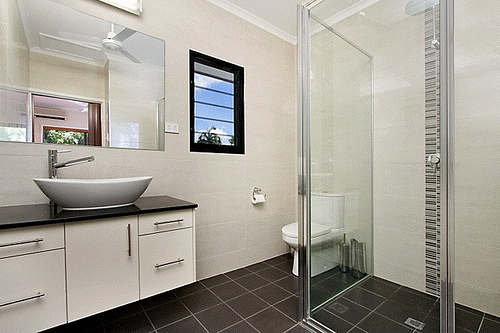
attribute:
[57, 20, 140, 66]
fan — white 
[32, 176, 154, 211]
sink — curved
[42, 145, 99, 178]
faucet — gray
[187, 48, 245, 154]
frame — black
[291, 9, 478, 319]
shower — glass 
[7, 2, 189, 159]
mirror — rectangular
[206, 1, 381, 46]
ceiling trim — white 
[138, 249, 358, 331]
tile — black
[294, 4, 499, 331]
shower — clear 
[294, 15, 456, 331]
door — glass 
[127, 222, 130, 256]
handle — silver 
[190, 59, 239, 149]
window — small 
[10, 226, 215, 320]
cabinets — white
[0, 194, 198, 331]
vanity — white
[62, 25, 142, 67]
ceiling fan — white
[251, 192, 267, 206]
toilet paper — white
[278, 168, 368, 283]
toilet — white 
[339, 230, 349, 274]
toiletbrush holder — black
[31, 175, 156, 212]
sink bowl — white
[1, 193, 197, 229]
counter — black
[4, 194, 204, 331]
cabinets — white 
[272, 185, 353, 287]
toilet — white 